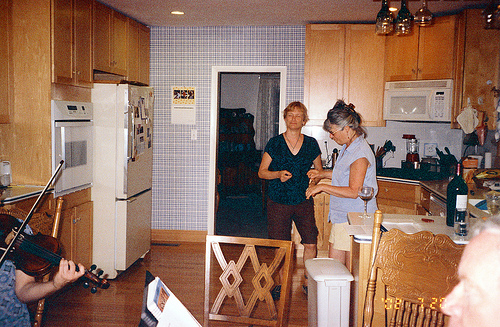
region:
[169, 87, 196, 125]
a calendar on wall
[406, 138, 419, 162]
a red electric blender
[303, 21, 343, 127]
a brown wood cabinet door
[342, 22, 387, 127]
a brown wood cabinet door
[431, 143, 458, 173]
a wooden knife block holder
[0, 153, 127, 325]
Person playing violin.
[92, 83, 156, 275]
White fridge with photos and notes.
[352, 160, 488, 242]
Counter with a bottle of wine and a glass.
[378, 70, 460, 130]
White built in microwave.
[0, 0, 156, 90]
Brown cabinets up high.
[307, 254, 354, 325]
White plastic trash can.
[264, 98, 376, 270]
Two women dancing in kitchen.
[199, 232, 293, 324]
Brown wooden kitchen chair.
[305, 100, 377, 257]
grey haired woman dancing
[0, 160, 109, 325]
person sitting and playing violin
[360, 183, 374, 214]
glass of red wine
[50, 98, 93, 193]
white finish wall mounted oven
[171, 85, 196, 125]
calendar hanging on wall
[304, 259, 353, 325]
white plastic trash can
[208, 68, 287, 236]
a kitchen doorway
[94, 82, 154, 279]
a white refrigerator freezer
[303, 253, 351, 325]
a white trash can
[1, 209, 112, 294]
a brown wood violin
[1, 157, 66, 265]
a violin bow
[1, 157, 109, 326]
a child playing the violin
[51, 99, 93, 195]
a white built in oven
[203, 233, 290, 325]
a brown wooden chair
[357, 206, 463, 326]
a brown wooden chair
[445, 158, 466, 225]
a bottle of wine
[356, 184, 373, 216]
a glass of wine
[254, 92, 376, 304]
two women in the kitchen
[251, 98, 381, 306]
women in the kitchen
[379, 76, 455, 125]
a white microwave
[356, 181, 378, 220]
a glass of wine on table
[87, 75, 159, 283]
a white refrigerator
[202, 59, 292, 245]
door in the kitchen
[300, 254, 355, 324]
a white trash bin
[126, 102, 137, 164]
a handle grip of the refrigerator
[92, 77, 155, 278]
A large white fridge.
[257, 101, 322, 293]
Light brown haired woman in green shirt and brown shorts.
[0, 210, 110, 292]
A brown violin.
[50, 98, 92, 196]
White stove in a brown wall.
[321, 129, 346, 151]
the face of a woman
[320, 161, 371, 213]
the arm of a woman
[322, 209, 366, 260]
the shorts of a woman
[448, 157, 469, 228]
bottle of wine sitting on the counter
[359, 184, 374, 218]
nearly empty wine glass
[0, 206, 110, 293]
a person playing the violen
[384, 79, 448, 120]
white above-the-range microwave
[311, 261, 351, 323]
white plastic trash can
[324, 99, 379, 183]
woman in a gray shirt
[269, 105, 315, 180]
woman in a green and black shirt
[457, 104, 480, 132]
pot holders hanging from the cabinet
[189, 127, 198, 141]
a white light switch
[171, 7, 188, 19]
recessed light in the ceiling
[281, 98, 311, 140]
the head of a woman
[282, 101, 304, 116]
the hair of a woman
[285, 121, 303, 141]
the neck of a woman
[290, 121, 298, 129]
the mouth of a woman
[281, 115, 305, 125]
the nose of a woman